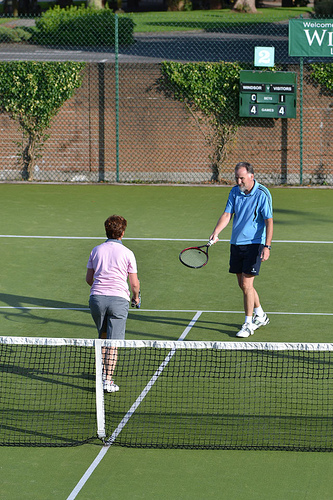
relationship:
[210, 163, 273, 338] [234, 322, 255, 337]
man wearing tennis shoe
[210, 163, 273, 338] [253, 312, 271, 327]
man wearing tennis shoe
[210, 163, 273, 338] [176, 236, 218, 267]
man holding racket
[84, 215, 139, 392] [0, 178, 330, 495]
person on tennis court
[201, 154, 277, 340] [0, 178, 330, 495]
person on tennis court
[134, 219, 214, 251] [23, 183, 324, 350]
line painted on court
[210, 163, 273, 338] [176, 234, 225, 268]
man sticking out h racket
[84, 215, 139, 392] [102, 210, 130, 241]
person has brownhair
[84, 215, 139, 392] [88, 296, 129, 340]
person wearing shorts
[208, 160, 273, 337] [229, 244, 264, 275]
person wearing short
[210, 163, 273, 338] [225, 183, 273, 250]
man wearing shirt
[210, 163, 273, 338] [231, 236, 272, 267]
man wearing shorts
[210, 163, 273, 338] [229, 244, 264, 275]
man wearing short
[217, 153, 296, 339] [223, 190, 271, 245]
man wearing blue shirt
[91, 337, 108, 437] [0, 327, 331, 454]
line vertically aligned with net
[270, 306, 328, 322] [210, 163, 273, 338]
line behind man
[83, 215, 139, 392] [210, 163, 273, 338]
woman facing man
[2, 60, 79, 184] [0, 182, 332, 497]
trees near court